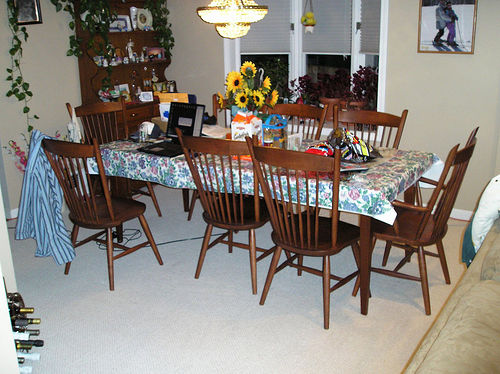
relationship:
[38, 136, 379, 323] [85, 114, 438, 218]
chairs on table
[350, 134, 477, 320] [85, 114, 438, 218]
chairs on table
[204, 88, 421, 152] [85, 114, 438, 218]
chairs on table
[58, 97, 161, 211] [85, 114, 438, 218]
chairs on table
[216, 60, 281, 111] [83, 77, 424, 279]
daisies on table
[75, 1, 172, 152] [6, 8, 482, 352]
bookcase in dining room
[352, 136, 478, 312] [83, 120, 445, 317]
chairs at head of table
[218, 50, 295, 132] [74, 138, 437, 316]
daisies on top of table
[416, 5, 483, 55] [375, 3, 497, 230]
people photo on wall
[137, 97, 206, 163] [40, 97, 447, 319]
laptop computer on table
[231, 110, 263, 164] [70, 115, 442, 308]
goldfish carton on table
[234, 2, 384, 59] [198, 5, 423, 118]
blinds on window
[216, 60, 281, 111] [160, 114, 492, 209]
daisies on table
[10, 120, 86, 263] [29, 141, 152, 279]
shirt on chair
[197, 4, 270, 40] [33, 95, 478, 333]
light over table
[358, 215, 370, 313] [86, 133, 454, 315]
leg on table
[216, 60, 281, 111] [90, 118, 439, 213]
daisies on table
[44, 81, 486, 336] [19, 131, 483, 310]
table with chairs